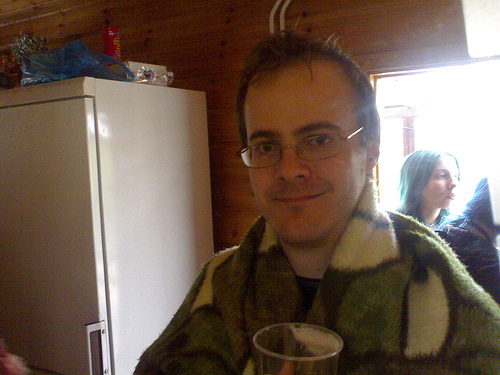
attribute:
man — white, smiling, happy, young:
[130, 29, 499, 375]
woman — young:
[392, 151, 459, 235]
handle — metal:
[79, 317, 107, 373]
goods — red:
[99, 20, 123, 60]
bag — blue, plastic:
[10, 31, 136, 82]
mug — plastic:
[251, 318, 348, 374]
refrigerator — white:
[0, 75, 218, 374]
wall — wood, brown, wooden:
[2, 2, 468, 252]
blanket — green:
[128, 177, 497, 374]